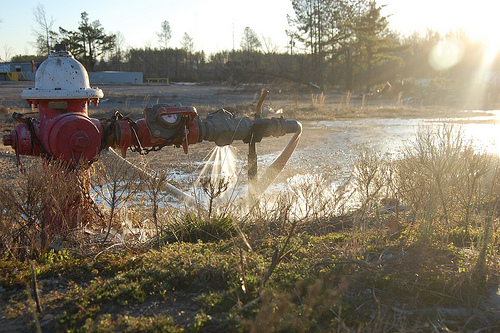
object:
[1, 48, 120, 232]
hydrant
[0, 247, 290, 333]
field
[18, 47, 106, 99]
cap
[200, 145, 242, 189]
water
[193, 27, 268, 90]
trees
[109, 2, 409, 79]
background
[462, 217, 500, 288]
branches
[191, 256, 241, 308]
grass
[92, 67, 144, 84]
building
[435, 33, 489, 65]
glare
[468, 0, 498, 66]
light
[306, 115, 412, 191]
large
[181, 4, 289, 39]
bright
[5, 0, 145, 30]
skies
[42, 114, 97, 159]
red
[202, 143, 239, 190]
out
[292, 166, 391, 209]
bare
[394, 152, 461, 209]
bushes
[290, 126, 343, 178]
reservoir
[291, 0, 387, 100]
group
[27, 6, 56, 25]
bare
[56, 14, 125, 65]
tree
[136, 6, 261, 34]
sky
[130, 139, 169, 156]
chain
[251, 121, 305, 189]
fire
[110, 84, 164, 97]
clearing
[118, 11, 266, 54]
horizon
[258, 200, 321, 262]
weeds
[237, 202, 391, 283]
bank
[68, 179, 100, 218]
chains